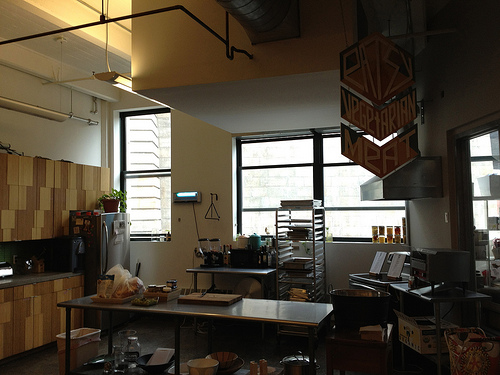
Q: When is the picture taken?
A: Daytime.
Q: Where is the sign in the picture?
A: Top right.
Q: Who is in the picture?
A: No one.